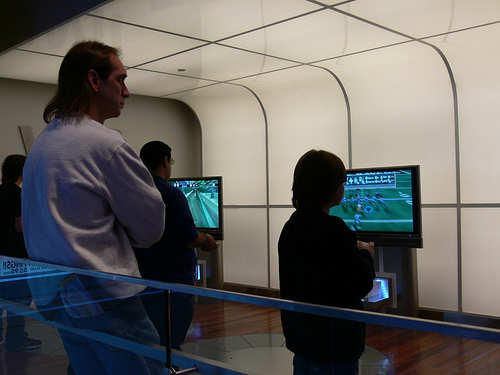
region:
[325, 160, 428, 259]
the televisions are on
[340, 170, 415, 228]
game on the tv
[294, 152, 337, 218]
the hair is dark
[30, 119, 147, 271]
the shirt is white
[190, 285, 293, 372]
the floors are wooden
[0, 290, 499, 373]
the shiny wood floor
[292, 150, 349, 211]
the dark colored hair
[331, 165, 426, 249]
the tv is turned on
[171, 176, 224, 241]
the tv is turned on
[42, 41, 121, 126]
the long dark brown hair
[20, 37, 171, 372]
the man with his arms crossed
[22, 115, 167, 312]
the long sleeved gray shirt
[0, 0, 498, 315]
the lit up wall and ceiling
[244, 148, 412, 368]
a person standing inside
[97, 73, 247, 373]
a person standin ginside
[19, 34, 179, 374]
a person wearing a sweater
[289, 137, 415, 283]
a tv that is turned on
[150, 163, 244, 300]
a tv turned on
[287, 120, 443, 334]
a game on a tv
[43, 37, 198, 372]
The man is leaning against the railing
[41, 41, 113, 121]
The man has long hair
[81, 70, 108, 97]
The ear of the man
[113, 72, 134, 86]
The eye of the man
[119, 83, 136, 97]
The nose of the man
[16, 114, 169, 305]
The man is wearing a long sleeved shirt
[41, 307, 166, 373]
The man is wearing a jean pant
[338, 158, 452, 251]
The tv is displaying a game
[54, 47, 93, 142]
hair is touching shirt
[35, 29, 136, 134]
the head of a man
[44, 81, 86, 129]
the hair of a man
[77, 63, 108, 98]
the ear of a man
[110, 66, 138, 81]
the brows of a man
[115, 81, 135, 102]
the nose of a man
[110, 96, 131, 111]
the mouth of a man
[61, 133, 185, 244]
the arm of a man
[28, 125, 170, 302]
the shirt of a man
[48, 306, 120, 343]
the pockets of a man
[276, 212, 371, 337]
boy wearing a black shirt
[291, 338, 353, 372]
boy wearing black pants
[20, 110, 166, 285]
man wearing a grey shirt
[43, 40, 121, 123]
man with brown hair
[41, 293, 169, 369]
man wearing blue jeans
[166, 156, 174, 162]
man wearing reading glasses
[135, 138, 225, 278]
man playing a video game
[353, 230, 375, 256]
man holding a controller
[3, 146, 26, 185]
man with black hair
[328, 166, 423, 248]
green game screen with black frame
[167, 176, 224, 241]
green game screen with black frame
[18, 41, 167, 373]
man leaning against a clear glass counter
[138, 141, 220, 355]
man watching the screen wearing eye glasses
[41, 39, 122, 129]
black thinning shoulder length hair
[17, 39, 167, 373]
man wearing a white sweatchirt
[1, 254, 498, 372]
clear glass counter top with silver railings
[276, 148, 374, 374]
person wearing black outfit looking at monitor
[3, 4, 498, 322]
white reflective wall with crossed black lines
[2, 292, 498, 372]
brown and black wood floor